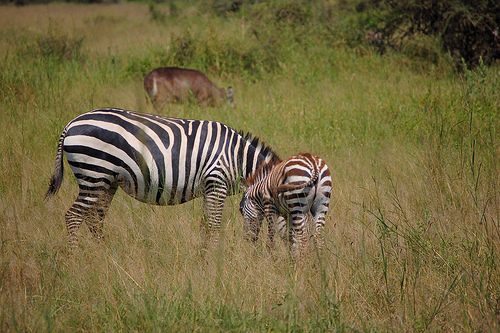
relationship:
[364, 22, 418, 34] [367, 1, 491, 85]
branches of tree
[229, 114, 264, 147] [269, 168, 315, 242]
mane of zebra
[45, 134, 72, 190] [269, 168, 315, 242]
tail of zebra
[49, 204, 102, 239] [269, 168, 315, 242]
leg of zebra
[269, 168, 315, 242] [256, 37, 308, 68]
zebra in field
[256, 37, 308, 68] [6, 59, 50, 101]
field of grass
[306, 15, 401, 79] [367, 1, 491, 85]
shadow under tree